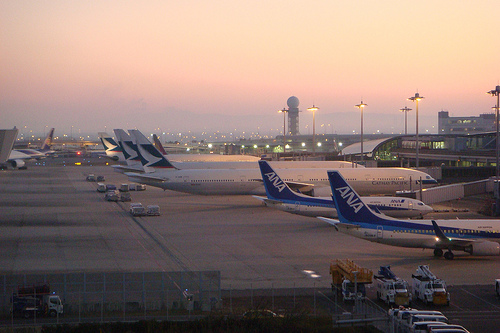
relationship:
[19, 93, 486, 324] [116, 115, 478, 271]
airport with planes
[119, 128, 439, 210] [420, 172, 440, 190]
airplane has nose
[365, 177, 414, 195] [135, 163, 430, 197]
logo on white airplane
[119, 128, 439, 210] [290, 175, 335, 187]
airplane has windows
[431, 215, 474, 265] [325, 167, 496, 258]
wings airplane on airplane